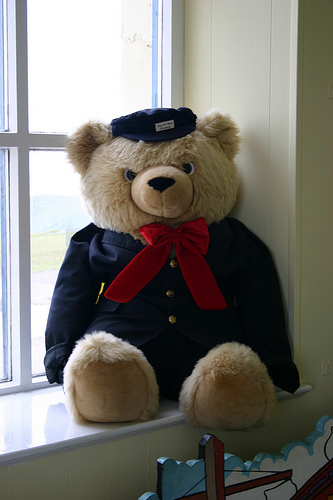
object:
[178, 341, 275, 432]
foot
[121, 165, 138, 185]
eye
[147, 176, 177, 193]
nose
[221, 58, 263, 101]
ground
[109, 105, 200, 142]
cap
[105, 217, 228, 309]
bow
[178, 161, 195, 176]
left eye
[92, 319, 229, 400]
shorts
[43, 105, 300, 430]
bear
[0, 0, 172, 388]
frame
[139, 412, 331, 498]
display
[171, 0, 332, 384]
wall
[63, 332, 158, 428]
foot